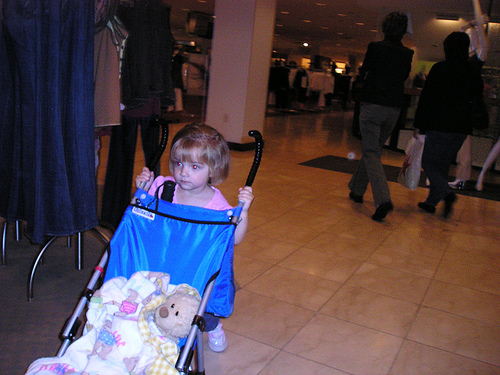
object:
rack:
[1, 219, 112, 302]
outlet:
[171, 36, 355, 113]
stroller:
[55, 118, 265, 374]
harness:
[103, 189, 243, 319]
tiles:
[244, 225, 499, 363]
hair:
[168, 122, 230, 185]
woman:
[347, 11, 415, 221]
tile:
[317, 283, 425, 340]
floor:
[399, 301, 500, 366]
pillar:
[206, 0, 277, 152]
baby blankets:
[25, 270, 201, 375]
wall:
[216, 86, 244, 99]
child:
[135, 122, 257, 353]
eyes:
[175, 162, 200, 170]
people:
[411, 31, 489, 213]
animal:
[154, 287, 203, 339]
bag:
[397, 134, 426, 192]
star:
[399, 155, 411, 177]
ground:
[0, 136, 500, 373]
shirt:
[147, 175, 233, 210]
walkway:
[0, 109, 500, 375]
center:
[265, 101, 353, 133]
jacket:
[351, 39, 414, 107]